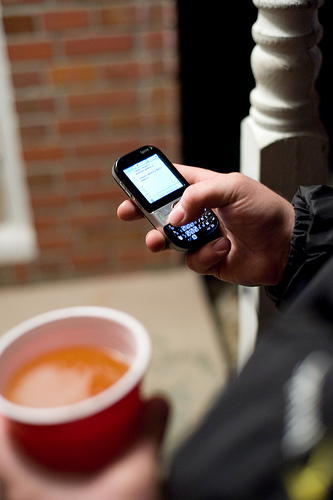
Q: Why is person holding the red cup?
A: Thirsty.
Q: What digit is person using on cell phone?
A: Thumb.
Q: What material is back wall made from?
A: Brick.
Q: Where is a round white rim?
A: On red cup.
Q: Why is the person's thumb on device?
A: Pressing button.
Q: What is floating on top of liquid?
A: Foam.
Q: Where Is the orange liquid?
A: Red cup.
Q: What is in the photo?
A: A phone.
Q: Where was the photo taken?
A: In a room.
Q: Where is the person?
A: In a room.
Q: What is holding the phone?
A: A hand.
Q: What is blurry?
A: The drinking cup.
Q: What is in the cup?
A: Liquid.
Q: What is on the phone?
A: Buttons.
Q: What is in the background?
A: Bricks.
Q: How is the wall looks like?
A: Blurry.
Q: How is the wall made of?
A: Bricks.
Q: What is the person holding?
A: Cup.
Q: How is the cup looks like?
A: Red.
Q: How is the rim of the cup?
A: White.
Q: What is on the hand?
A: Cellphone.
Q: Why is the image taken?
A: Remembrance.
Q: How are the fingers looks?
A: Good.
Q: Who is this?
A: Person.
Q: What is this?
A: Phone.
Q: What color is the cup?
A: Red.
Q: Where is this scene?
A: In a living room.